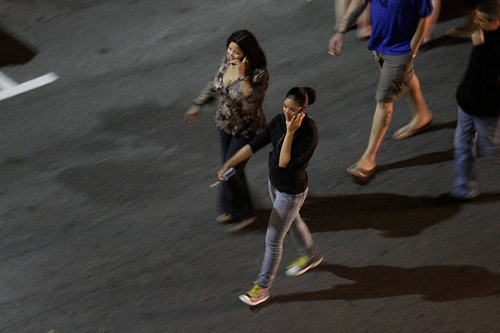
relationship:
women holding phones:
[184, 30, 324, 307] [230, 52, 307, 121]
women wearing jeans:
[209, 88, 324, 307] [256, 177, 316, 286]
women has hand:
[209, 88, 324, 307] [218, 162, 232, 184]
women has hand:
[209, 88, 324, 307] [285, 112, 306, 136]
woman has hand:
[183, 26, 267, 232] [183, 104, 203, 124]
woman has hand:
[183, 26, 267, 232] [230, 54, 249, 74]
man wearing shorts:
[327, 1, 433, 180] [370, 49, 414, 100]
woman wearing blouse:
[183, 26, 267, 232] [193, 56, 267, 135]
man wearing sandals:
[327, 1, 433, 180] [347, 114, 433, 183]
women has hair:
[209, 88, 324, 307] [284, 84, 316, 106]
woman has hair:
[183, 26, 267, 232] [226, 29, 267, 69]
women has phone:
[209, 88, 324, 307] [294, 107, 305, 118]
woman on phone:
[183, 26, 267, 232] [230, 53, 246, 67]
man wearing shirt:
[440, 4, 499, 201] [457, 29, 499, 118]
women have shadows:
[184, 30, 324, 307] [249, 193, 498, 313]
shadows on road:
[249, 193, 498, 313] [0, 0, 499, 331]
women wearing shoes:
[209, 88, 324, 307] [238, 249, 323, 305]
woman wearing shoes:
[183, 26, 267, 232] [215, 210, 259, 232]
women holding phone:
[209, 88, 324, 307] [294, 107, 305, 118]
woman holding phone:
[183, 26, 267, 232] [230, 53, 246, 67]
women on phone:
[184, 30, 324, 307] [230, 53, 246, 67]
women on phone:
[184, 30, 324, 307] [294, 107, 305, 118]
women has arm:
[209, 88, 324, 307] [217, 113, 280, 181]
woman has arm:
[183, 26, 267, 232] [183, 80, 216, 125]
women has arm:
[209, 88, 324, 307] [278, 115, 319, 169]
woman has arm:
[183, 26, 267, 232] [230, 54, 269, 110]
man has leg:
[327, 1, 433, 180] [391, 74, 433, 142]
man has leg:
[440, 4, 499, 201] [474, 115, 499, 161]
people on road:
[184, 1, 499, 307] [0, 0, 499, 331]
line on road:
[1, 70, 60, 104] [0, 0, 499, 331]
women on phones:
[184, 30, 324, 307] [230, 52, 307, 121]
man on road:
[327, 1, 433, 180] [0, 0, 499, 331]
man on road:
[440, 4, 499, 201] [0, 0, 499, 331]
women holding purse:
[209, 88, 324, 307] [210, 166, 236, 189]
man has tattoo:
[327, 1, 433, 180] [382, 110, 392, 127]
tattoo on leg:
[382, 110, 392, 127] [346, 54, 414, 183]